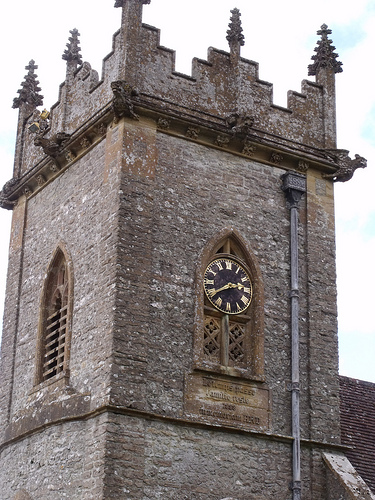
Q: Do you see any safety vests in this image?
A: No, there are no safety vests.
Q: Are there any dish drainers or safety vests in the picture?
A: No, there are no safety vests or dish drainers.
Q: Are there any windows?
A: Yes, there is a window.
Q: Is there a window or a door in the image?
A: Yes, there is a window.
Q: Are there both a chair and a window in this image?
A: No, there is a window but no chairs.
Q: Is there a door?
A: No, there are no doors.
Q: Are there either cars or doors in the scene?
A: No, there are no doors or cars.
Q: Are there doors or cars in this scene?
A: No, there are no doors or cars.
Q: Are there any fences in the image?
A: No, there are no fences.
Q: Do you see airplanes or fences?
A: No, there are no fences or airplanes.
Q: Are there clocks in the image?
A: Yes, there is a clock.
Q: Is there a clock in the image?
A: Yes, there is a clock.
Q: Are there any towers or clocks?
A: Yes, there is a clock.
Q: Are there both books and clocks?
A: No, there is a clock but no books.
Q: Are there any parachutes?
A: No, there are no parachutes.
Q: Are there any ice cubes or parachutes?
A: No, there are no parachutes or ice cubes.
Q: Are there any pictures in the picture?
A: No, there are no pictures.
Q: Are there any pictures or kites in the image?
A: No, there are no pictures or kites.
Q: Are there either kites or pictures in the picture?
A: No, there are no pictures or kites.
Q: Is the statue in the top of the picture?
A: Yes, the statue is in the top of the image.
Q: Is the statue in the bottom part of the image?
A: No, the statue is in the top of the image.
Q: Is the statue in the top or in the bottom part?
A: The statue is in the top of the image.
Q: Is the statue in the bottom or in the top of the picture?
A: The statue is in the top of the image.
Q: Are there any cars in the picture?
A: No, there are no cars.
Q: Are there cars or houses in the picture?
A: No, there are no cars or houses.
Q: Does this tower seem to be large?
A: Yes, the tower is large.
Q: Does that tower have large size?
A: Yes, the tower is large.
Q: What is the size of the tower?
A: The tower is large.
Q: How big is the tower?
A: The tower is large.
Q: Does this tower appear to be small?
A: No, the tower is large.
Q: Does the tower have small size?
A: No, the tower is large.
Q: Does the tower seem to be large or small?
A: The tower is large.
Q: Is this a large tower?
A: Yes, this is a large tower.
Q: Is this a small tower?
A: No, this is a large tower.